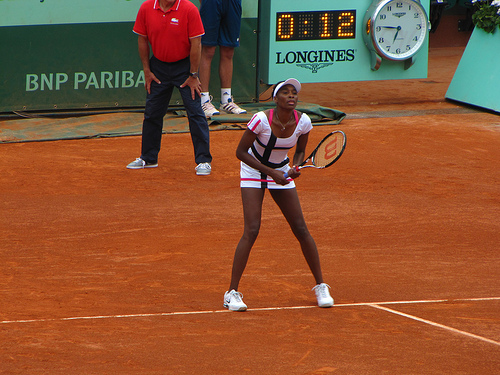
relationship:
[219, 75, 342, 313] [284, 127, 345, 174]
venus holds racket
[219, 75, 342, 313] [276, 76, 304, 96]
venus wears visor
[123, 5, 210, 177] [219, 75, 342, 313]
line judge behind venus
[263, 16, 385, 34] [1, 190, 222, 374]
clock behind court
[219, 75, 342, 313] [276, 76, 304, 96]
venus has visor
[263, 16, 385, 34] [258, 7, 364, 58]
clock shows time